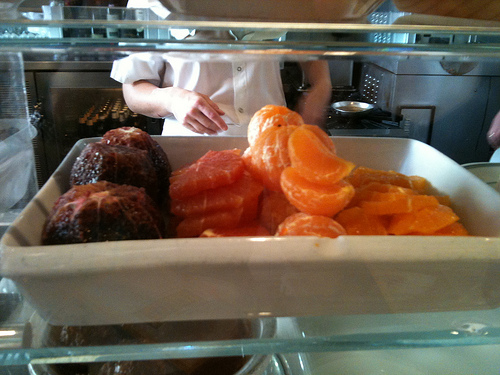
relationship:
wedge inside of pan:
[290, 125, 349, 188] [13, 237, 499, 319]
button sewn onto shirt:
[238, 66, 245, 74] [138, 56, 284, 114]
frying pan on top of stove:
[328, 92, 382, 122] [328, 122, 402, 135]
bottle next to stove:
[87, 119, 92, 134] [328, 122, 402, 135]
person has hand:
[119, 61, 345, 133] [172, 88, 229, 133]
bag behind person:
[28, 22, 53, 36] [119, 61, 345, 133]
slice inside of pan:
[284, 187, 348, 210] [13, 237, 499, 319]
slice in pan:
[284, 218, 335, 238] [13, 237, 499, 319]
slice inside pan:
[251, 107, 275, 131] [13, 237, 499, 319]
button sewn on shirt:
[238, 66, 245, 74] [138, 56, 284, 114]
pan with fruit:
[13, 237, 499, 319] [46, 180, 160, 239]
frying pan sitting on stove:
[328, 92, 382, 122] [328, 122, 402, 135]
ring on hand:
[309, 118, 314, 119] [298, 104, 333, 125]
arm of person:
[128, 80, 166, 118] [119, 61, 345, 133]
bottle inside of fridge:
[115, 98, 121, 102] [39, 74, 100, 103]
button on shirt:
[238, 66, 245, 74] [138, 56, 284, 114]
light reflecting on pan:
[412, 148, 450, 178] [13, 237, 499, 319]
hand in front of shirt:
[172, 88, 229, 133] [138, 56, 284, 114]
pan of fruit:
[13, 237, 499, 319] [46, 180, 160, 239]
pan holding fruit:
[13, 237, 499, 319] [46, 180, 160, 239]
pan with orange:
[13, 237, 499, 319] [370, 167, 456, 235]